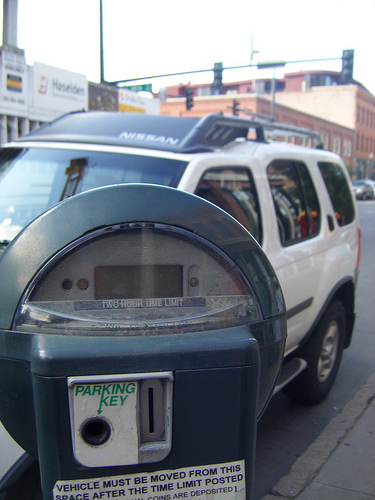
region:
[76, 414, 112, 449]
hole for the parking key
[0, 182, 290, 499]
blue parking meter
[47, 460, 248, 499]
notification on parking meter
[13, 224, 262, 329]
time display area on a parking meter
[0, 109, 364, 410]
white vehicle behind the parking meter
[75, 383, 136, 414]
green letters on the parking meter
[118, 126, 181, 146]
the word Nissan on the top of the white vehicle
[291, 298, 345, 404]
back tire on the white vehicle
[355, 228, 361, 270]
tail light on the white vehicle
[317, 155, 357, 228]
rear window on the vehicle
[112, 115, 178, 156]
THE SUV IS NISSAN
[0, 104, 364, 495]
THE SUV IS WHITE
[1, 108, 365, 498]
THIS IS A SUV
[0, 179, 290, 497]
THE PARKING METER IS GREY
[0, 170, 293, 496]
THE PARKING METER IS DIGITAL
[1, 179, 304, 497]
THIS IS A PARKING METER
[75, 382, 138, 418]
THE PARKING METER SAYS PARKING KEY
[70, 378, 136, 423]
TH WORDS ARE GREEN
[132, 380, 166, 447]
THIS IS THE COIN SLOT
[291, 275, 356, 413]
THE TIRES ARE BLACK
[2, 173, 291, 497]
Grey parking meter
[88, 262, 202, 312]
Blank parking meter screen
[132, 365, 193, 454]
coin slot on a parking meter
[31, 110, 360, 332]
White Nissan SUV behind a parking meter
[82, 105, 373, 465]
A White Nissan Pathfinder parked at a meter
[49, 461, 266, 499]
A notice on a parking meter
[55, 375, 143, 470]
A parking key reader on a meter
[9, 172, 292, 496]
A parking meter on the sidewalk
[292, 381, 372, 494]
The curb of a street and sidewalk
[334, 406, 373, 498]
The sidewalk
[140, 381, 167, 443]
slot to put change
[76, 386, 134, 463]
parking key sign on meter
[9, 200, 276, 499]
parking meter to park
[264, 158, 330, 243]
window of white vehicle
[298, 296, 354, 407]
black tire with chrome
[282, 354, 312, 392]
step to get up into vehicle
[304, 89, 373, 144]
part of a brown building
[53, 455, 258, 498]
white sign with black words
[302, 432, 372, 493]
gray sidewalk next to the road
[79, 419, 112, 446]
key hole for a key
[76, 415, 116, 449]
Slot for parking key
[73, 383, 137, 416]
Green parking key writing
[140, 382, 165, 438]
Coin slot on meter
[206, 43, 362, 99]
Traffic signals on pole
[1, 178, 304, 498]
Parking meter on sidewalk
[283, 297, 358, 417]
Rear tire on SUV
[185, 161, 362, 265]
Side windows of SUV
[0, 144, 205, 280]
Windshield of white SUV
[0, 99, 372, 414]
White SUV parked at meter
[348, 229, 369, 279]
Tail light of white SUV